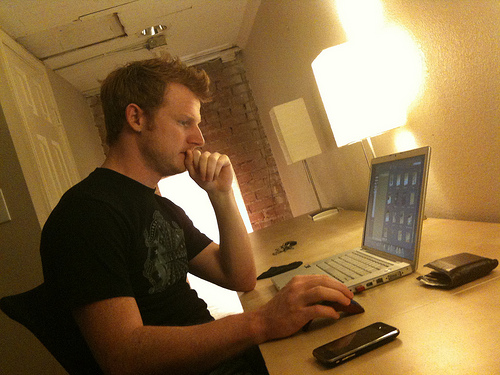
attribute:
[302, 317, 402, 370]
cell phone — black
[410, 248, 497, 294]
wallet — black, leather, closed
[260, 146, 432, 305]
laptop — silver, white, open, o, gray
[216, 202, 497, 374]
table — wood, brown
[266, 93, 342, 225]
lamp — off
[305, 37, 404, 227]
lamp — on, bright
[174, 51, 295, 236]
wall — brick, red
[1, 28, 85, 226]
door — white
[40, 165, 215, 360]
shirt — black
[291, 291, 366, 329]
mouse — curved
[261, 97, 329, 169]
shade — white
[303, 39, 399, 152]
shade — white, on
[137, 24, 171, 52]
light fixture — metal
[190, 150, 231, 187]
fingers — folded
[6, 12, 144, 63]
tile — lifted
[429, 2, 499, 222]
wall — white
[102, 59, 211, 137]
hair — orange